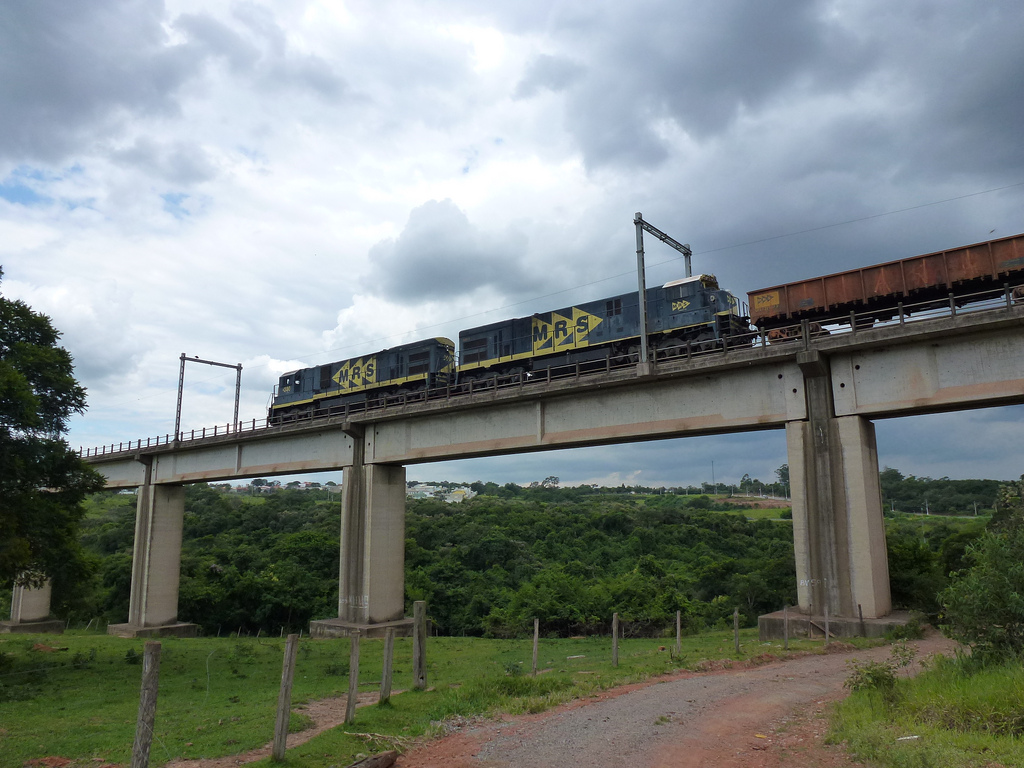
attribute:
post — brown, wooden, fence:
[132, 643, 186, 767]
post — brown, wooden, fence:
[261, 627, 296, 764]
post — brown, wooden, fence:
[319, 619, 361, 714]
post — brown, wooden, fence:
[366, 621, 409, 699]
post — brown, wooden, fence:
[376, 600, 427, 686]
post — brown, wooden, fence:
[515, 606, 545, 684]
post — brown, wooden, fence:
[607, 612, 626, 673]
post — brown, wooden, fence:
[659, 597, 691, 661]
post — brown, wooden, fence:
[701, 583, 746, 661]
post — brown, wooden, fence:
[808, 596, 870, 641]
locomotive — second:
[458, 253, 731, 397]